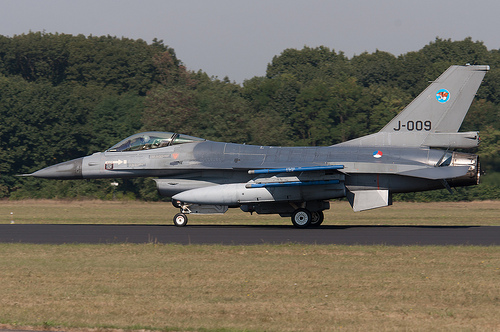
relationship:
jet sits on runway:
[20, 58, 471, 239] [22, 211, 474, 246]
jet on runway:
[20, 58, 471, 239] [22, 211, 474, 246]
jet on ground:
[20, 58, 471, 239] [8, 191, 497, 321]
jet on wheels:
[20, 58, 471, 239] [169, 208, 329, 239]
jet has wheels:
[20, 58, 471, 239] [169, 208, 329, 239]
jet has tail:
[20, 58, 471, 239] [393, 36, 472, 146]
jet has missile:
[20, 58, 471, 239] [176, 175, 336, 207]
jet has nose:
[20, 58, 471, 239] [0, 137, 57, 200]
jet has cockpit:
[20, 58, 471, 239] [111, 118, 184, 154]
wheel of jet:
[166, 205, 194, 231] [12, 63, 491, 226]